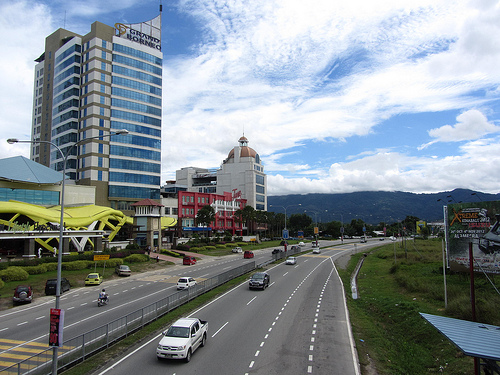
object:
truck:
[223, 280, 275, 325]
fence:
[35, 258, 255, 356]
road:
[106, 230, 396, 375]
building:
[29, 5, 164, 218]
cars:
[83, 272, 105, 286]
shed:
[0, 155, 71, 188]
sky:
[160, 29, 500, 193]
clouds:
[428, 108, 499, 146]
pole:
[54, 168, 66, 313]